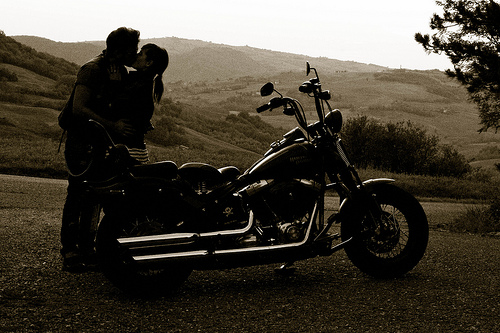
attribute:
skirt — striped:
[118, 126, 170, 186]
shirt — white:
[116, 78, 160, 179]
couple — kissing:
[55, 18, 182, 255]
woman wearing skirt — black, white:
[102, 142, 162, 177]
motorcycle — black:
[77, 65, 429, 277]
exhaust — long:
[111, 204, 333, 269]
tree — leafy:
[408, 1, 500, 142]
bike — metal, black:
[68, 60, 434, 281]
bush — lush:
[337, 105, 473, 190]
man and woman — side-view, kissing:
[49, 20, 177, 270]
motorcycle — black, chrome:
[65, 60, 450, 308]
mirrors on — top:
[250, 58, 326, 96]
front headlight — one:
[326, 109, 358, 134]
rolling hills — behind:
[2, 29, 285, 175]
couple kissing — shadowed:
[41, 26, 175, 277]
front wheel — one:
[337, 181, 451, 289]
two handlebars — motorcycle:
[245, 76, 335, 120]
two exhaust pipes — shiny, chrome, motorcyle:
[110, 193, 331, 276]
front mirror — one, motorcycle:
[297, 58, 323, 78]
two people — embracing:
[44, 23, 177, 246]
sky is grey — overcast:
[4, 3, 481, 80]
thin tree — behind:
[409, 1, 498, 127]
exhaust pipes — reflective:
[106, 194, 338, 265]